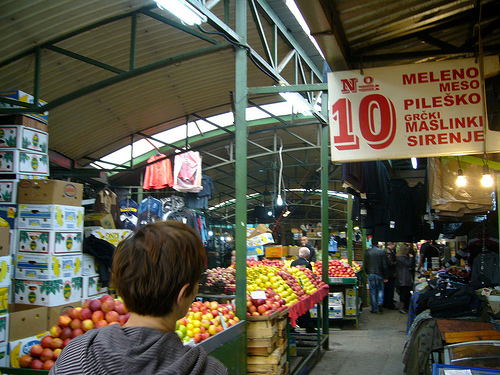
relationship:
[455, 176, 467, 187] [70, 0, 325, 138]
bulb hanging from ceiling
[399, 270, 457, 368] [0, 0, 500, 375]
man shopping at market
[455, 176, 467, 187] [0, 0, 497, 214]
bulb hanging from ceiling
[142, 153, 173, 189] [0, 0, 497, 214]
clothes hanging from ceiling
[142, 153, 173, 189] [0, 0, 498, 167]
clothes hanging from ceiling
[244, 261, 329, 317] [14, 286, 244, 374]
fruit stacked on table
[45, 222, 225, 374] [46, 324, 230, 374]
person wearing hoodie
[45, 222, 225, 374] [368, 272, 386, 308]
person wearing jeans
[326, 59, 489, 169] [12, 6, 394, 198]
sign hanging from ceiling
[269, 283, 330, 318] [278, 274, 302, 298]
table covered in apples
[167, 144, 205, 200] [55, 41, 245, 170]
shirt hanging from ceiling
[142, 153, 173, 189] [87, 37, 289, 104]
clothes hanging from ceiling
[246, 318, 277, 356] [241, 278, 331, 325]
box under table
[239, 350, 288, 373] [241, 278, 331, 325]
box under table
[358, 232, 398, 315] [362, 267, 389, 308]
man wearing jeans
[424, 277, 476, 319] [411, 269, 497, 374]
clothes on table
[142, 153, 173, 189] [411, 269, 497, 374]
clothes on table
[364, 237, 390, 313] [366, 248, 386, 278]
man wears jacket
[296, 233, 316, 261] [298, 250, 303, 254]
man has hair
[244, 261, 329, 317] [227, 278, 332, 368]
fruit on table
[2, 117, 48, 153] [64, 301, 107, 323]
box of fruit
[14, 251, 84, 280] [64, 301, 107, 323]
box of fruit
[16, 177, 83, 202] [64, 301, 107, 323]
box of fruit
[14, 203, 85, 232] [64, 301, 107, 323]
bins of fruit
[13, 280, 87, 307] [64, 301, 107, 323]
box of fruit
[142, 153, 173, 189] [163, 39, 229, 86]
clothes handing from ceiling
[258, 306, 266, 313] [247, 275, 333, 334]
peach on table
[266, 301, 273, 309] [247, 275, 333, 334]
peach on table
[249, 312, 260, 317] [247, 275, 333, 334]
peach on table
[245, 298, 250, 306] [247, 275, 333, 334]
peach on table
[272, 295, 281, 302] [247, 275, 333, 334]
peach on table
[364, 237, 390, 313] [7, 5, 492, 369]
man in market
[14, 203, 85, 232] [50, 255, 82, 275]
bins of a bananas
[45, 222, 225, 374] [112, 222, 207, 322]
person has short hair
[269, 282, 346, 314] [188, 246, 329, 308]
table full of fruit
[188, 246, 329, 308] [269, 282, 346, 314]
fruit on table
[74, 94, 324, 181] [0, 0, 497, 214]
skylight in ceiling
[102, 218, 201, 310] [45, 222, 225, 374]
head on person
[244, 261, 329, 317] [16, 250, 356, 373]
fruit in bins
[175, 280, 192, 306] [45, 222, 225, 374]
ear on person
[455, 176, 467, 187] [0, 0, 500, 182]
bulb hanging from building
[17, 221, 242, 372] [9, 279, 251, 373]
person standing next to table